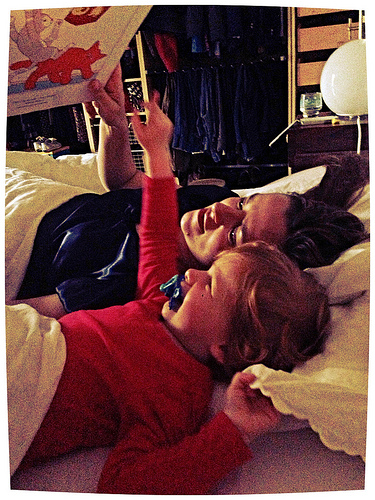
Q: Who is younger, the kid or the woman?
A: The kid is younger than the woman.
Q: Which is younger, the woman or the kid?
A: The kid is younger than the woman.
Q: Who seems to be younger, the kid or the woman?
A: The kid is younger than the woman.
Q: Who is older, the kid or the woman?
A: The woman is older than the kid.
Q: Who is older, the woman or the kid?
A: The woman is older than the kid.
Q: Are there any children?
A: Yes, there is a child.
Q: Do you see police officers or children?
A: Yes, there is a child.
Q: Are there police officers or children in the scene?
A: Yes, there is a child.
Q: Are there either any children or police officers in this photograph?
A: Yes, there is a child.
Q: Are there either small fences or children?
A: Yes, there is a small child.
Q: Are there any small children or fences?
A: Yes, there is a small child.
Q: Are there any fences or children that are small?
A: Yes, the child is small.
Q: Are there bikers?
A: No, there are no bikers.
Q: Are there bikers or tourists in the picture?
A: No, there are no bikers or tourists.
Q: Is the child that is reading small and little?
A: Yes, the child is small and little.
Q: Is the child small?
A: Yes, the child is small.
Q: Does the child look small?
A: Yes, the child is small.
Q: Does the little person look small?
A: Yes, the child is small.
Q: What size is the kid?
A: The kid is small.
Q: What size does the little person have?
A: The kid has small size.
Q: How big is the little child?
A: The child is small.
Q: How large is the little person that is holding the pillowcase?
A: The child is small.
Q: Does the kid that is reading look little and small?
A: Yes, the child is little and small.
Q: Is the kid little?
A: Yes, the kid is little.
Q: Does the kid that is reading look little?
A: Yes, the kid is little.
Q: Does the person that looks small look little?
A: Yes, the kid is little.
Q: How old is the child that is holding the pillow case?
A: The child is little.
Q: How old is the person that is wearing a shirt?
A: The child is little.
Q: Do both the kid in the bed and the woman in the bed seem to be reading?
A: Yes, both the child and the woman are reading.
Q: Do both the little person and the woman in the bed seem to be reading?
A: Yes, both the child and the woman are reading.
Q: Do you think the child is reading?
A: Yes, the child is reading.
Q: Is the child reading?
A: Yes, the child is reading.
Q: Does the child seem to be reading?
A: Yes, the child is reading.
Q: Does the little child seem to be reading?
A: Yes, the child is reading.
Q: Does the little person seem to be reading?
A: Yes, the child is reading.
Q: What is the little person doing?
A: The child is reading.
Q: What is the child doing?
A: The child is reading.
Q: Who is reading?
A: The kid is reading.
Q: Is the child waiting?
A: No, the child is reading.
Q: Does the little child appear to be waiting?
A: No, the child is reading.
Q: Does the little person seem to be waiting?
A: No, the child is reading.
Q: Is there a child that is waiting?
A: No, there is a child but he is reading.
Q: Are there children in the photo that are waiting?
A: No, there is a child but he is reading.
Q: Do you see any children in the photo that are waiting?
A: No, there is a child but he is reading.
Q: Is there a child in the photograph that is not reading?
A: No, there is a child but he is reading.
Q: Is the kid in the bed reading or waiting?
A: The child is reading.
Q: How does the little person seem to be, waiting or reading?
A: The child is reading.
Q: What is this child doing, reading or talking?
A: The child is reading.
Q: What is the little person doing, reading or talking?
A: The child is reading.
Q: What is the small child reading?
A: The child is reading a book.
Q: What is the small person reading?
A: The child is reading a book.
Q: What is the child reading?
A: The child is reading a book.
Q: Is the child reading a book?
A: Yes, the child is reading a book.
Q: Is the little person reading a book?
A: Yes, the child is reading a book.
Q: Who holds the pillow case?
A: The kid holds the pillow case.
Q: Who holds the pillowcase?
A: The kid holds the pillow case.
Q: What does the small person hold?
A: The child holds the pillowcase.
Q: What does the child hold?
A: The child holds the pillowcase.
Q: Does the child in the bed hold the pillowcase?
A: Yes, the child holds the pillowcase.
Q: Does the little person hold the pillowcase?
A: Yes, the child holds the pillowcase.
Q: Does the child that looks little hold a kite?
A: No, the kid holds the pillowcase.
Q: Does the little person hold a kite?
A: No, the kid holds the pillowcase.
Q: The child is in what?
A: The child is in the bed.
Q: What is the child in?
A: The child is in the bed.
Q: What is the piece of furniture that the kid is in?
A: The piece of furniture is a bed.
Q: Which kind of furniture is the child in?
A: The kid is in the bed.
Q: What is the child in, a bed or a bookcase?
A: The child is in a bed.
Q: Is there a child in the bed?
A: Yes, there is a child in the bed.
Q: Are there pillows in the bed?
A: No, there is a child in the bed.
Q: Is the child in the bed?
A: Yes, the child is in the bed.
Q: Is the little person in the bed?
A: Yes, the child is in the bed.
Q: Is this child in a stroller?
A: No, the child is in the bed.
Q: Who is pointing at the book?
A: The child is pointing at the book.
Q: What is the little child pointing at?
A: The child is pointing at the book.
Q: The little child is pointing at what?
A: The child is pointing at the book.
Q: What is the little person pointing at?
A: The child is pointing at the book.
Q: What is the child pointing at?
A: The child is pointing at the book.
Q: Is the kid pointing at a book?
A: Yes, the kid is pointing at a book.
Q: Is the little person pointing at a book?
A: Yes, the kid is pointing at a book.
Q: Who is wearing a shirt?
A: The kid is wearing a shirt.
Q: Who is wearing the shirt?
A: The kid is wearing a shirt.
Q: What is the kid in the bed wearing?
A: The child is wearing a shirt.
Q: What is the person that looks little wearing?
A: The child is wearing a shirt.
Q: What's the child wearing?
A: The child is wearing a shirt.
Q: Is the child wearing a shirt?
A: Yes, the child is wearing a shirt.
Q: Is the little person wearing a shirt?
A: Yes, the child is wearing a shirt.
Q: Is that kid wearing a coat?
A: No, the kid is wearing a shirt.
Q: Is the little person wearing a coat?
A: No, the kid is wearing a shirt.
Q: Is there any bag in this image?
A: No, there are no bags.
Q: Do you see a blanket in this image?
A: Yes, there is a blanket.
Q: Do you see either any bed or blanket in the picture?
A: Yes, there is a blanket.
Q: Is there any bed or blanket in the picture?
A: Yes, there is a blanket.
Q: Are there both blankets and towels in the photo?
A: No, there is a blanket but no towels.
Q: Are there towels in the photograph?
A: No, there are no towels.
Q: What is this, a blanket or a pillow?
A: This is a blanket.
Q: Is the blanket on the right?
A: No, the blanket is on the left of the image.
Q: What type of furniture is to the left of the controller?
A: The piece of furniture is a closet.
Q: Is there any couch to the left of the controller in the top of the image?
A: No, there is a closet to the left of the controller.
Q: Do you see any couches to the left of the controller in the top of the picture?
A: No, there is a closet to the left of the controller.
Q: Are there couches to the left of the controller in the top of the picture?
A: No, there is a closet to the left of the controller.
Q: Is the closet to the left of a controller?
A: Yes, the closet is to the left of a controller.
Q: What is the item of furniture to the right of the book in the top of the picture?
A: The piece of furniture is a closet.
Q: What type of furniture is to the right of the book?
A: The piece of furniture is a closet.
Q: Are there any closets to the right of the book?
A: Yes, there is a closet to the right of the book.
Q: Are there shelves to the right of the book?
A: No, there is a closet to the right of the book.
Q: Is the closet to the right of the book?
A: Yes, the closet is to the right of the book.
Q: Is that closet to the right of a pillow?
A: No, the closet is to the right of the book.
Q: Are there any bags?
A: No, there are no bags.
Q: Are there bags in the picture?
A: No, there are no bags.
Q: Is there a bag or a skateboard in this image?
A: No, there are no bags or skateboards.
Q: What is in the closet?
A: The jeans are in the closet.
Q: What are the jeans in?
A: The jeans are in the closet.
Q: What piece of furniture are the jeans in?
A: The jeans are in the closet.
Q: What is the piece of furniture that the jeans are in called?
A: The piece of furniture is a closet.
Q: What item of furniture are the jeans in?
A: The jeans are in the closet.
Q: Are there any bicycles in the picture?
A: No, there are no bicycles.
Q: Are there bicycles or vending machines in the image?
A: No, there are no bicycles or vending machines.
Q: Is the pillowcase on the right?
A: Yes, the pillowcase is on the right of the image.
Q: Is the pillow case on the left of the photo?
A: No, the pillow case is on the right of the image.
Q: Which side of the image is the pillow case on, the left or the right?
A: The pillow case is on the right of the image.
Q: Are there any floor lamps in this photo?
A: No, there are no floor lamps.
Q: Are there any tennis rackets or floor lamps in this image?
A: No, there are no floor lamps or tennis rackets.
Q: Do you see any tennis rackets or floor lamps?
A: No, there are no floor lamps or tennis rackets.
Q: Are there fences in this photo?
A: No, there are no fences.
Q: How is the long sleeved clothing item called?
A: The clothing item is a shirt.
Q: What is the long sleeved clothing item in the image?
A: The clothing item is a shirt.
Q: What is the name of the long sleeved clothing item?
A: The clothing item is a shirt.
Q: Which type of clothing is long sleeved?
A: The clothing is a shirt.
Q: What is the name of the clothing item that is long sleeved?
A: The clothing item is a shirt.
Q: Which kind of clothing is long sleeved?
A: The clothing is a shirt.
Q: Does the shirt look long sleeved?
A: Yes, the shirt is long sleeved.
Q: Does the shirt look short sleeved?
A: No, the shirt is long sleeved.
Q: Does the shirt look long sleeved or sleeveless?
A: The shirt is long sleeved.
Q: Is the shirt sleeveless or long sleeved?
A: The shirt is long sleeved.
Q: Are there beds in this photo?
A: Yes, there is a bed.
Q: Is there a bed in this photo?
A: Yes, there is a bed.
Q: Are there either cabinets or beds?
A: Yes, there is a bed.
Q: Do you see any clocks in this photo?
A: No, there are no clocks.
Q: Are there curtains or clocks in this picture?
A: No, there are no clocks or curtains.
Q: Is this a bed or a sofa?
A: This is a bed.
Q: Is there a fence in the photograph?
A: No, there are no fences.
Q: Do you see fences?
A: No, there are no fences.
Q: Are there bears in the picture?
A: No, there are no bears.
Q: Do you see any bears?
A: No, there are no bears.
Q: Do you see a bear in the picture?
A: No, there are no bears.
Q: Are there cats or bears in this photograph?
A: No, there are no bears or cats.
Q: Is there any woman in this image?
A: Yes, there is a woman.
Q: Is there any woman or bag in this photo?
A: Yes, there is a woman.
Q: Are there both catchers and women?
A: No, there is a woman but no catchers.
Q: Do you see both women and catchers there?
A: No, there is a woman but no catchers.